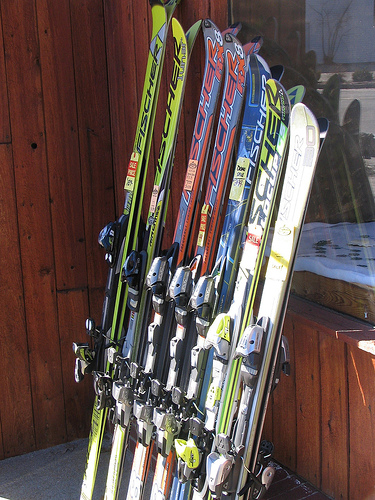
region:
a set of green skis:
[74, 3, 187, 497]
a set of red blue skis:
[124, 15, 240, 497]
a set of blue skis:
[163, 51, 283, 497]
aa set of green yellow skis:
[198, 73, 306, 497]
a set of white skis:
[213, 97, 333, 497]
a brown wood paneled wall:
[1, 0, 110, 462]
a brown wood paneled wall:
[111, 0, 228, 249]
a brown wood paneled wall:
[258, 284, 372, 497]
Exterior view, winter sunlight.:
[6, 10, 367, 493]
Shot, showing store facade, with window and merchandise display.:
[1, 0, 372, 497]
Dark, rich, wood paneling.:
[8, 75, 74, 420]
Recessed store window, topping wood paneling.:
[210, 5, 371, 312]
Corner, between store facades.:
[88, 9, 130, 393]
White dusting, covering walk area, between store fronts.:
[12, 431, 118, 495]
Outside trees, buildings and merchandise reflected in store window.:
[261, 10, 372, 282]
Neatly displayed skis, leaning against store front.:
[82, 56, 312, 496]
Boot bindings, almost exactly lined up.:
[80, 233, 268, 480]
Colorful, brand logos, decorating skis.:
[129, 64, 332, 294]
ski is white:
[283, 212, 295, 262]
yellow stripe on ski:
[266, 253, 297, 272]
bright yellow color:
[142, 106, 152, 145]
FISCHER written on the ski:
[139, 48, 170, 143]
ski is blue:
[208, 201, 240, 243]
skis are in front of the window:
[273, 270, 322, 341]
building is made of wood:
[20, 210, 85, 289]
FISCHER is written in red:
[212, 67, 239, 198]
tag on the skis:
[240, 155, 244, 201]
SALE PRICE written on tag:
[125, 158, 140, 177]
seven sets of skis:
[52, 10, 332, 497]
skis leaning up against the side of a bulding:
[46, 22, 327, 498]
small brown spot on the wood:
[308, 373, 317, 382]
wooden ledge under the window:
[288, 297, 374, 353]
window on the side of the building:
[214, 8, 373, 326]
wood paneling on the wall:
[3, 2, 129, 460]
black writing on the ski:
[126, 46, 163, 151]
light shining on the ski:
[260, 154, 309, 310]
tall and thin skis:
[70, 3, 318, 498]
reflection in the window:
[262, 54, 373, 249]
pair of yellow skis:
[79, 40, 136, 496]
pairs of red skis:
[103, 53, 266, 495]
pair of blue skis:
[159, 93, 267, 496]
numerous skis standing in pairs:
[83, 94, 332, 477]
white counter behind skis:
[278, 228, 373, 297]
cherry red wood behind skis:
[279, 279, 373, 464]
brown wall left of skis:
[3, 25, 128, 360]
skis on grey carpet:
[11, 437, 86, 497]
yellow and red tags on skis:
[118, 139, 280, 263]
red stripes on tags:
[111, 162, 222, 264]